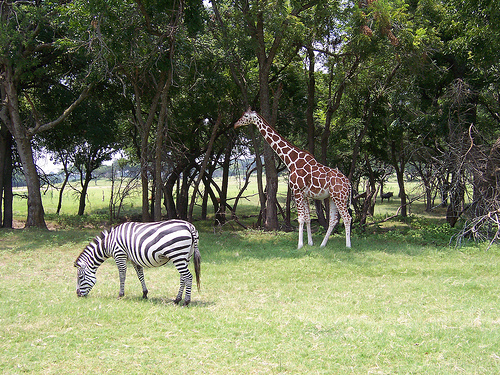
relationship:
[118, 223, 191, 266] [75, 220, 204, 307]
stripes are on zebra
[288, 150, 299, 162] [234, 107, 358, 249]
spot on giraffe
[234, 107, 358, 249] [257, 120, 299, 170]
giraffe has neck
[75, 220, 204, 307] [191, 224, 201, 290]
zebra has tail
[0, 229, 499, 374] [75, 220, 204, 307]
grass being eaten by zebra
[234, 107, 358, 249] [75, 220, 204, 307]
giraffe near to zebra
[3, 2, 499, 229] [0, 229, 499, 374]
trees are behind grass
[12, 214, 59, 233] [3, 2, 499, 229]
dirt near trees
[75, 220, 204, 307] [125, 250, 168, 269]
zebra has belly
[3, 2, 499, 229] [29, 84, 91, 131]
trees have branch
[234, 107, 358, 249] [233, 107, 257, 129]
giraffe has head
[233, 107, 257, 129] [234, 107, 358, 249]
head on giraffe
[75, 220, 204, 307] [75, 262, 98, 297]
zebra has head